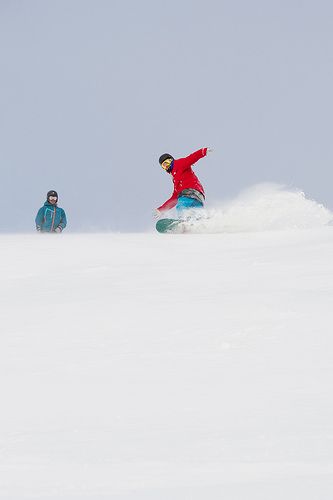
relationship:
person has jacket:
[159, 144, 208, 220] [159, 150, 206, 212]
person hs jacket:
[37, 192, 68, 232] [36, 203, 67, 233]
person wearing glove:
[37, 192, 68, 232] [54, 227, 59, 235]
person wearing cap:
[159, 144, 208, 220] [158, 155, 172, 163]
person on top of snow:
[159, 144, 208, 220] [4, 180, 329, 499]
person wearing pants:
[159, 144, 208, 220] [175, 198, 202, 212]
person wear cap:
[159, 144, 208, 220] [158, 155, 172, 163]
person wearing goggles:
[159, 144, 208, 220] [161, 159, 173, 168]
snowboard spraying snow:
[156, 220, 179, 235] [4, 180, 329, 499]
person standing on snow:
[159, 144, 208, 220] [4, 180, 329, 499]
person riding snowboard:
[159, 144, 208, 220] [156, 220, 179, 235]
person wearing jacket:
[159, 144, 208, 220] [159, 150, 206, 212]